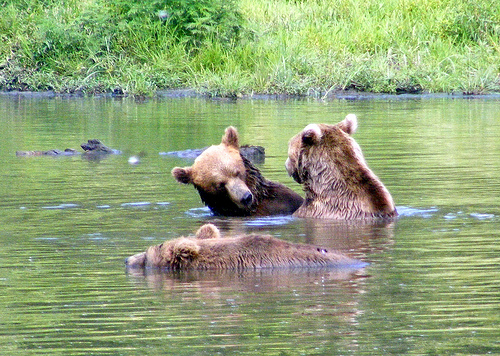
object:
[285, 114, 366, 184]
head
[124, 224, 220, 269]
head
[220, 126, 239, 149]
ear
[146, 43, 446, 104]
bank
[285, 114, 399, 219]
bear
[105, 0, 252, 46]
leaves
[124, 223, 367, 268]
bear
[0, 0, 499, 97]
grass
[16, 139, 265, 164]
rocks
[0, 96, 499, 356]
water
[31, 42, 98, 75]
bushes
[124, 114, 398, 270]
three bears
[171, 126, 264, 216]
head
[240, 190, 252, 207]
nose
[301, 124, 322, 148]
ear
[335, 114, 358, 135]
ear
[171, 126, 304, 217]
bear